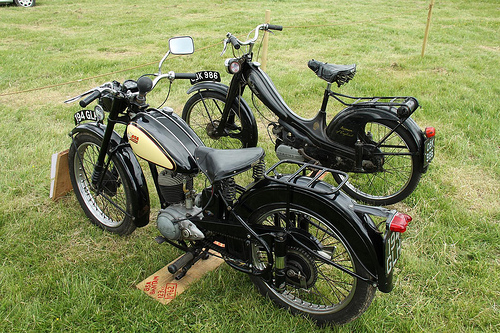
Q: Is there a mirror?
A: Yes, there is a mirror.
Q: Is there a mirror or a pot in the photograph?
A: Yes, there is a mirror.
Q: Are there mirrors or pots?
A: Yes, there is a mirror.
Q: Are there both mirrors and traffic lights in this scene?
A: No, there is a mirror but no traffic lights.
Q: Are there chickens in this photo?
A: No, there are no chickens.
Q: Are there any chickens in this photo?
A: No, there are no chickens.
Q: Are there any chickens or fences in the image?
A: No, there are no chickens or fences.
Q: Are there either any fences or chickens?
A: No, there are no chickens or fences.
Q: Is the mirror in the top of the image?
A: Yes, the mirror is in the top of the image.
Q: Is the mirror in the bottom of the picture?
A: No, the mirror is in the top of the image.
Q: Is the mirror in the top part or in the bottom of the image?
A: The mirror is in the top of the image.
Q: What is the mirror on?
A: The mirror is on the bike.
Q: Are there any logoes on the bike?
A: No, there is a mirror on the bike.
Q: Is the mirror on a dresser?
A: No, the mirror is on the bike.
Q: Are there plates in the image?
A: Yes, there is a plate.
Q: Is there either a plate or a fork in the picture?
A: Yes, there is a plate.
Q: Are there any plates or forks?
A: Yes, there is a plate.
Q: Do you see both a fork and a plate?
A: No, there is a plate but no forks.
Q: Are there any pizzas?
A: No, there are no pizzas.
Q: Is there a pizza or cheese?
A: No, there are no pizzas or cheese.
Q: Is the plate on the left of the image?
A: No, the plate is on the right of the image.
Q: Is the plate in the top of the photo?
A: No, the plate is in the bottom of the image.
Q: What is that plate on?
A: The plate is on the bike.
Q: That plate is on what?
A: The plate is on the bike.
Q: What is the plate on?
A: The plate is on the bike.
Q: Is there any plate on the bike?
A: Yes, there is a plate on the bike.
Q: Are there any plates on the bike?
A: Yes, there is a plate on the bike.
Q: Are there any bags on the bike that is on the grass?
A: No, there is a plate on the bike.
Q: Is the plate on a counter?
A: No, the plate is on the bike.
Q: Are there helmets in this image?
A: No, there are no helmets.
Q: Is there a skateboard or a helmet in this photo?
A: No, there are no helmets or skateboards.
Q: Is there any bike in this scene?
A: Yes, there is a bike.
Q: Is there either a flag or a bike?
A: Yes, there is a bike.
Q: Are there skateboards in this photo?
A: No, there are no skateboards.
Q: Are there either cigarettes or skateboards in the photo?
A: No, there are no skateboards or cigarettes.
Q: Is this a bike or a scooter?
A: This is a bike.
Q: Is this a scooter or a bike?
A: This is a bike.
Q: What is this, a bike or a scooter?
A: This is a bike.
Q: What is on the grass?
A: The bike is on the grass.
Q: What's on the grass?
A: The bike is on the grass.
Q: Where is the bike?
A: The bike is on the grass.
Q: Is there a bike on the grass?
A: Yes, there is a bike on the grass.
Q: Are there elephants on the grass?
A: No, there is a bike on the grass.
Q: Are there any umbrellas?
A: No, there are no umbrellas.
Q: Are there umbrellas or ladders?
A: No, there are no umbrellas or ladders.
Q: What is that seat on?
A: The seat is on the bike.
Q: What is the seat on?
A: The seat is on the bike.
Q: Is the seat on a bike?
A: Yes, the seat is on a bike.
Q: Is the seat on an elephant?
A: No, the seat is on a bike.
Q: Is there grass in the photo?
A: Yes, there is grass.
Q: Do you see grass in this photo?
A: Yes, there is grass.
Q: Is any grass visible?
A: Yes, there is grass.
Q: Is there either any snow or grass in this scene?
A: Yes, there is grass.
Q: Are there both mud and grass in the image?
A: No, there is grass but no mud.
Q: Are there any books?
A: No, there are no books.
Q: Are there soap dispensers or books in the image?
A: No, there are no books or soap dispensers.